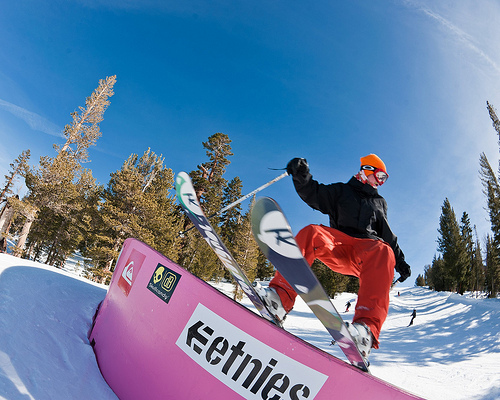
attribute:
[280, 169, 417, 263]
jacket — black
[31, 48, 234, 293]
trees — tall, green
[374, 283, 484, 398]
snow — white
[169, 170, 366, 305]
sign — black, white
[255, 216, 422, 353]
pants — orange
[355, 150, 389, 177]
hat — orange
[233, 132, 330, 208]
gloves — black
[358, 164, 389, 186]
goggles — red, silver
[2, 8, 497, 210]
sky — clear, blue